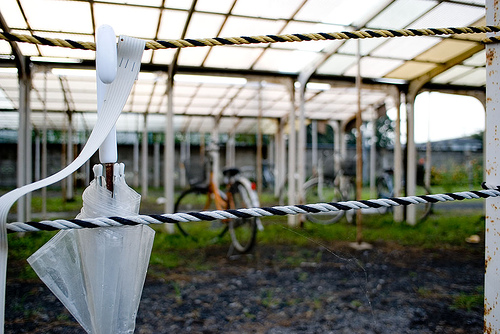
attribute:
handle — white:
[92, 19, 122, 168]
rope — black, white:
[5, 180, 496, 220]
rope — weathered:
[4, 25, 495, 47]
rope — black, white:
[7, 186, 495, 233]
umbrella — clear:
[33, 32, 145, 332]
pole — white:
[162, 57, 179, 237]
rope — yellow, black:
[154, 25, 482, 51]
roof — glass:
[1, 3, 498, 142]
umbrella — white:
[32, 45, 179, 331]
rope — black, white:
[0, 22, 499, 46]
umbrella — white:
[26, 23, 153, 332]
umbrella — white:
[33, 170, 160, 332]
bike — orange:
[176, 137, 265, 241]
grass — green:
[303, 232, 445, 240]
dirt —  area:
[0, 246, 497, 331]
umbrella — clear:
[4, 27, 157, 331]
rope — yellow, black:
[139, 16, 406, 50]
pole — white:
[479, 1, 498, 331]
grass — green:
[157, 187, 491, 238]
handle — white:
[72, 25, 141, 169]